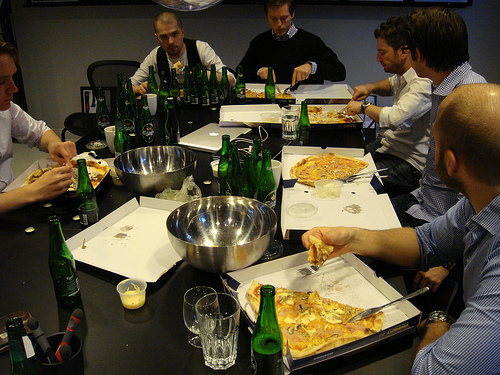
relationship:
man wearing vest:
[124, 11, 238, 96] [144, 57, 217, 107]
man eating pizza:
[369, 83, 499, 365] [33, 79, 425, 364]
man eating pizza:
[392, 3, 489, 243] [33, 79, 425, 364]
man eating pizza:
[349, 15, 430, 184] [33, 79, 425, 364]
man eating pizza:
[230, 1, 346, 85] [33, 79, 425, 364]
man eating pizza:
[128, 12, 233, 100] [33, 79, 425, 364]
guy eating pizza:
[0, 42, 77, 215] [33, 79, 425, 364]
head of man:
[432, 76, 499, 202] [301, 82, 498, 373]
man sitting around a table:
[367, 8, 489, 279] [10, 84, 408, 373]